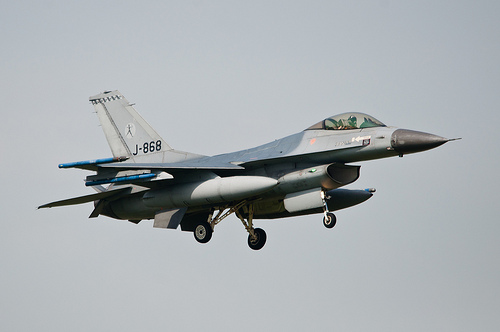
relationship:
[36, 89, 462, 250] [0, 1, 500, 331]
airplane flying in air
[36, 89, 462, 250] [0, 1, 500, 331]
airplane high in air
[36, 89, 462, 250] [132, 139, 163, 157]
airplane has identification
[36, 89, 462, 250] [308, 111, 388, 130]
airplane has cockpit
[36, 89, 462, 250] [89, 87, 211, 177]
airplane has tail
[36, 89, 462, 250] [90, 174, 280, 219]
airplane has missile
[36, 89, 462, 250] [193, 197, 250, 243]
airplane has landing gear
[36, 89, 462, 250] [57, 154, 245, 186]
airplane has wing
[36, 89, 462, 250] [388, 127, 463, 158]
airplane has nose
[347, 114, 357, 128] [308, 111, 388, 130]
pilot sitting in cockpit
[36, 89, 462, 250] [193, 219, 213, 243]
airplane has wheel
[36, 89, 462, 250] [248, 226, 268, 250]
airplane has wheel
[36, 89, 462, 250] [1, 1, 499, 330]
airplane flying in sky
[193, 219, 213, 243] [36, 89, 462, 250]
wheel on bottom of airplane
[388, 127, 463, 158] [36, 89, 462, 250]
nose on front of airplane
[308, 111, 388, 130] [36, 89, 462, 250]
cockpit on top of airplane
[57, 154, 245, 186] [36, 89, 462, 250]
wing on side of airplane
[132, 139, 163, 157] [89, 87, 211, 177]
identification on side of tail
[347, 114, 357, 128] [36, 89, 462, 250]
pilot piloting airplane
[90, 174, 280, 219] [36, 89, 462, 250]
missile on side of airplane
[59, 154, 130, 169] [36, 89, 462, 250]
weapon on side of airplane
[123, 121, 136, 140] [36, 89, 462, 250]
logo on side of airplane